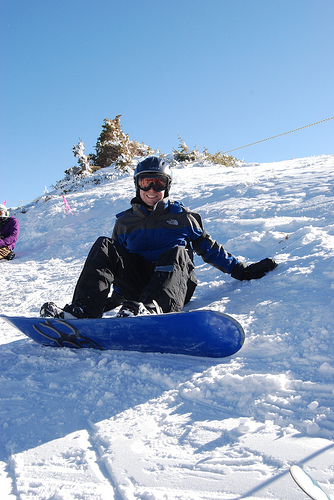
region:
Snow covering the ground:
[31, 422, 71, 467]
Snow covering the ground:
[76, 393, 128, 441]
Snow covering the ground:
[146, 459, 186, 485]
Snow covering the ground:
[220, 460, 250, 485]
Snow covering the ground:
[192, 404, 254, 442]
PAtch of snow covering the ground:
[23, 192, 46, 215]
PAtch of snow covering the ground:
[12, 339, 45, 376]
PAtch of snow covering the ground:
[35, 339, 82, 390]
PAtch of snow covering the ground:
[77, 345, 117, 379]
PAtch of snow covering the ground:
[111, 345, 154, 388]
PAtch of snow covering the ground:
[148, 348, 200, 401]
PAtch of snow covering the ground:
[184, 400, 247, 442]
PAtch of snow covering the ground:
[99, 419, 176, 470]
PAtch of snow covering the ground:
[50, 414, 120, 481]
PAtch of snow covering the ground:
[238, 436, 274, 470]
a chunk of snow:
[241, 364, 284, 397]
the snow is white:
[182, 425, 243, 470]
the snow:
[132, 439, 188, 472]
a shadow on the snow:
[20, 348, 80, 388]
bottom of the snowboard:
[183, 315, 220, 340]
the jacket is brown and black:
[129, 214, 172, 249]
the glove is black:
[248, 258, 276, 278]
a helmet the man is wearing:
[140, 161, 163, 171]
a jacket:
[128, 212, 170, 241]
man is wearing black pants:
[82, 257, 115, 288]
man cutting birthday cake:
[75, 420, 77, 422]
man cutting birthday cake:
[135, 442, 140, 446]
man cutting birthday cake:
[119, 457, 126, 462]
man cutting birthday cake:
[127, 441, 147, 448]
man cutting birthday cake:
[148, 448, 150, 450]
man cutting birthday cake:
[138, 463, 142, 467]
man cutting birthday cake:
[107, 431, 112, 435]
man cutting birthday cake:
[116, 469, 137, 476]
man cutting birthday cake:
[112, 448, 126, 458]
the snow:
[214, 370, 300, 444]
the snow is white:
[133, 441, 215, 486]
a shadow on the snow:
[60, 374, 114, 403]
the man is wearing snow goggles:
[132, 176, 167, 191]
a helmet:
[139, 159, 165, 171]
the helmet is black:
[136, 159, 162, 170]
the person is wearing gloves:
[241, 259, 271, 274]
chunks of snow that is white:
[245, 360, 299, 406]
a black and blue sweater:
[126, 210, 180, 245]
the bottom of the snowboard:
[165, 316, 234, 352]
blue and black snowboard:
[1, 308, 245, 358]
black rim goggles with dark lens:
[133, 172, 170, 193]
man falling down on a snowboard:
[0, 154, 279, 358]